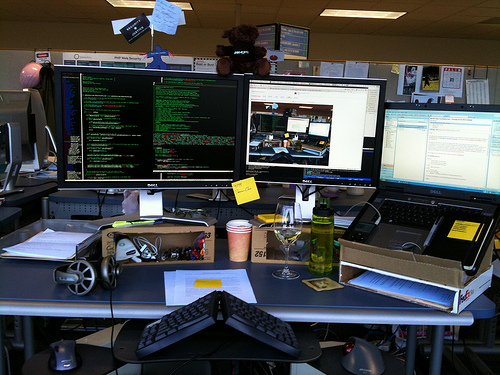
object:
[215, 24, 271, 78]
teddy bear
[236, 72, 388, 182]
black monitor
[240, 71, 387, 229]
computer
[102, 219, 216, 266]
stand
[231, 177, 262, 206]
note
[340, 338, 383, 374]
trackball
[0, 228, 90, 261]
paper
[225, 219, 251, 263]
cup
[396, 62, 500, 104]
board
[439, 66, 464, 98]
paper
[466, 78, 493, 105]
paper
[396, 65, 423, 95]
paper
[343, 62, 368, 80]
paper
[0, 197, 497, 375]
desk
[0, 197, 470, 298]
items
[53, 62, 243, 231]
computer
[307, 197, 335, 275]
bottle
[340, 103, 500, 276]
laptop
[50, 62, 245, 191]
computer screen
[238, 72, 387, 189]
computer screen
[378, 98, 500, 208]
computer screen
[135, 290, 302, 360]
keyboard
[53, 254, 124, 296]
head phones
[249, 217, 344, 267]
stand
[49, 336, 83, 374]
mouse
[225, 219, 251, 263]
paper cups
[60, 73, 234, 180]
code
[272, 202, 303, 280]
glass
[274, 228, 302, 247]
liquid